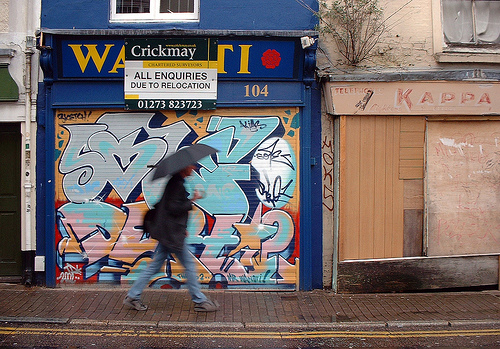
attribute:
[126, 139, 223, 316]
person — man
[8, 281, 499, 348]
sidewalk — uneven, dark red, brick, footpath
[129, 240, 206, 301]
jeans — blue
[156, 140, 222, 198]
umbrella — black colored, black in color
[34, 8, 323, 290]
building — blue colored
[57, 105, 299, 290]
graffiti — multicolor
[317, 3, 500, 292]
building — brown, boarded up, tan colored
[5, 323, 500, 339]
line — yellow in color, yellow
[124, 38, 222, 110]
sign — realty, yellow, black, writing